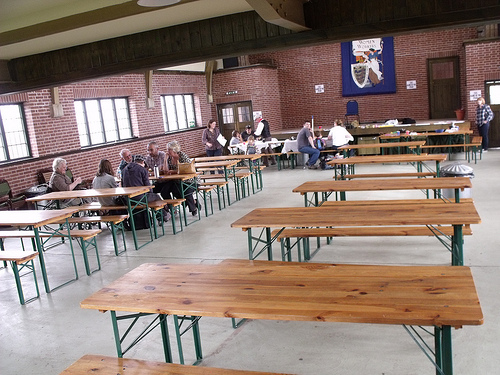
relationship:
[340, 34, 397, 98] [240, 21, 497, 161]
decorations on wall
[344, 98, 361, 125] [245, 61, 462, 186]
chair on stage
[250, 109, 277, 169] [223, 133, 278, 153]
person standing by table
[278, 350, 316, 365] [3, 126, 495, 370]
spot on floor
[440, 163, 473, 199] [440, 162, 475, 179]
can with can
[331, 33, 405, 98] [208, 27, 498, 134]
decorations hanging wall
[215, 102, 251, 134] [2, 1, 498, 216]
doors to building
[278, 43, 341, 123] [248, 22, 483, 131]
bricks on wall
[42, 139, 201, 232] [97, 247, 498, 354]
group sitting at table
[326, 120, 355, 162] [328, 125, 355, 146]
person wearing white shirt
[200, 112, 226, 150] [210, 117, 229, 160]
person carrying paper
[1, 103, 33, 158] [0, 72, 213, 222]
window on wall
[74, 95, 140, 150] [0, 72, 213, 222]
window on wall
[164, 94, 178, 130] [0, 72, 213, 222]
window on wall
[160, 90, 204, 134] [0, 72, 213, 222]
window on wall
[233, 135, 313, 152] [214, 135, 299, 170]
tablecloth on table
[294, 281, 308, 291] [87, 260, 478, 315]
spot on wood